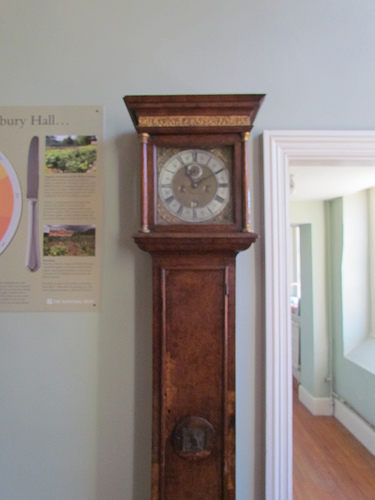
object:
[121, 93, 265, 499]
grandfather clock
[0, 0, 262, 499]
wall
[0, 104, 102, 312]
poster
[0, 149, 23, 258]
bowl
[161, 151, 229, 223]
numerals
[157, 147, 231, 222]
ring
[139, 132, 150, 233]
dowel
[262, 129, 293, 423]
molding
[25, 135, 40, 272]
knife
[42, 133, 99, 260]
picture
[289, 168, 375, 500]
hallway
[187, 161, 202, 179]
circle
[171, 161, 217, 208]
circle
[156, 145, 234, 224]
clockface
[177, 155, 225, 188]
11:10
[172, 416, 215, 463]
object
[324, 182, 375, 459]
wall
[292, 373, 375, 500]
floor boards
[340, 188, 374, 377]
window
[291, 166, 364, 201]
bulb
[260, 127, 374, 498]
door frame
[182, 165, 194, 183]
minute hand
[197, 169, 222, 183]
hour hand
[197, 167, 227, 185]
minute hand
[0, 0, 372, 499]
scene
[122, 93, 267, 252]
frame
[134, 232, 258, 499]
stand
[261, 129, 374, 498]
door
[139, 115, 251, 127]
trim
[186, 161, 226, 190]
square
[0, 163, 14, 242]
peach color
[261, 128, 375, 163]
door edge